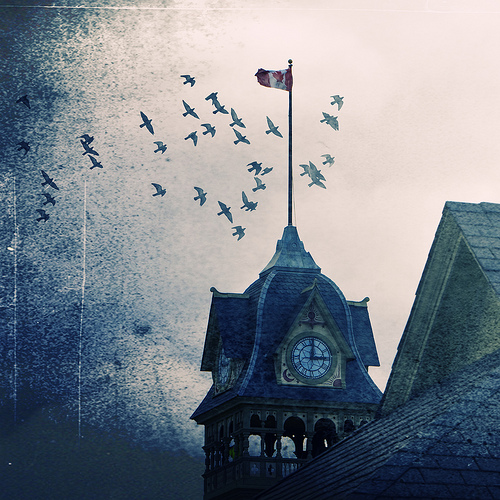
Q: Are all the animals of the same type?
A: Yes, all the animals are birds.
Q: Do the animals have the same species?
A: Yes, all the animals are birds.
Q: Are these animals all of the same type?
A: Yes, all the animals are birds.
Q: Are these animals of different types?
A: No, all the animals are birds.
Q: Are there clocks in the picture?
A: Yes, there is a clock.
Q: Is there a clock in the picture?
A: Yes, there is a clock.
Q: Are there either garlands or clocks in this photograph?
A: Yes, there is a clock.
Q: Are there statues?
A: No, there are no statues.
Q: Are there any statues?
A: No, there are no statues.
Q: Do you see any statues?
A: No, there are no statues.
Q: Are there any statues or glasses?
A: No, there are no statues or glasses.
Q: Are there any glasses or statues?
A: No, there are no statues or glasses.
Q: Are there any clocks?
A: Yes, there is a clock.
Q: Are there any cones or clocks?
A: Yes, there is a clock.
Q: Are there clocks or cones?
A: Yes, there is a clock.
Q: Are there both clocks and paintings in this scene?
A: No, there is a clock but no paintings.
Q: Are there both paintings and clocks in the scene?
A: No, there is a clock but no paintings.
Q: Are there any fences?
A: No, there are no fences.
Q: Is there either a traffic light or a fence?
A: No, there are no fences or traffic lights.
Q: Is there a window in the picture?
A: Yes, there are windows.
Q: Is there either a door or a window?
A: Yes, there are windows.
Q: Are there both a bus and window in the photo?
A: No, there are windows but no buses.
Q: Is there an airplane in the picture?
A: No, there are no airplanes.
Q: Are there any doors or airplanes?
A: No, there are no airplanes or doors.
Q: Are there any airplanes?
A: No, there are no airplanes.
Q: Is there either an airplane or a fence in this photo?
A: No, there are no airplanes or fences.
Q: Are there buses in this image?
A: No, there are no buses.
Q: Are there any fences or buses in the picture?
A: No, there are no buses or fences.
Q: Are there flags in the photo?
A: Yes, there is a flag.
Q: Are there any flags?
A: Yes, there is a flag.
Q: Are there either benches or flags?
A: Yes, there is a flag.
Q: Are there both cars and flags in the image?
A: No, there is a flag but no cars.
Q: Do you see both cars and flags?
A: No, there is a flag but no cars.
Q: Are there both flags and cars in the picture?
A: No, there is a flag but no cars.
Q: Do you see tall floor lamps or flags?
A: Yes, there is a tall flag.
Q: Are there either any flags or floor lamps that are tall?
A: Yes, the flag is tall.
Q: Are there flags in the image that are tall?
A: Yes, there is a tall flag.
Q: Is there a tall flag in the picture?
A: Yes, there is a tall flag.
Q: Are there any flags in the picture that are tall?
A: Yes, there is a flag that is tall.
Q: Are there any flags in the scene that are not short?
A: Yes, there is a tall flag.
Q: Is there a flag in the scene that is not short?
A: Yes, there is a tall flag.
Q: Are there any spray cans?
A: No, there are no spray cans.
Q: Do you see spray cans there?
A: No, there are no spray cans.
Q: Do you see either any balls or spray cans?
A: No, there are no spray cans or balls.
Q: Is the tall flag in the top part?
A: Yes, the flag is in the top of the image.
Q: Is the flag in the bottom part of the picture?
A: No, the flag is in the top of the image.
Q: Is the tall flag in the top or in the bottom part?
A: The flag is in the top of the image.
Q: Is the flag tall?
A: Yes, the flag is tall.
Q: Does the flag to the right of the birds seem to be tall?
A: Yes, the flag is tall.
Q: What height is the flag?
A: The flag is tall.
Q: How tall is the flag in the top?
A: The flag is tall.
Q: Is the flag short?
A: No, the flag is tall.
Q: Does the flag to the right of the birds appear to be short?
A: No, the flag is tall.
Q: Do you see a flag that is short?
A: No, there is a flag but it is tall.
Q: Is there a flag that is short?
A: No, there is a flag but it is tall.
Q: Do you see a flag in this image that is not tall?
A: No, there is a flag but it is tall.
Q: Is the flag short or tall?
A: The flag is tall.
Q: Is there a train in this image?
A: No, there are no trains.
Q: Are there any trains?
A: No, there are no trains.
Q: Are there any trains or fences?
A: No, there are no trains or fences.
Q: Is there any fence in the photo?
A: No, there are no fences.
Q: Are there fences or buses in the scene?
A: No, there are no fences or buses.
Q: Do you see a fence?
A: No, there are no fences.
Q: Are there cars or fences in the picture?
A: No, there are no fences or cars.